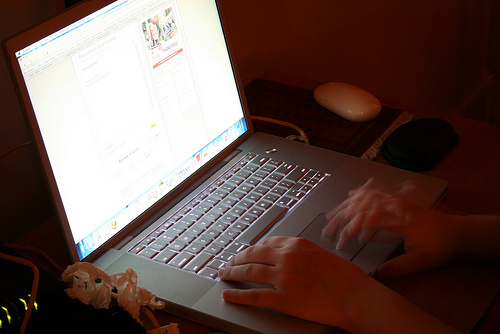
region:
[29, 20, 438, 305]
person working on lap top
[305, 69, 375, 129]
white computer mouse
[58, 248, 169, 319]
white tissue on side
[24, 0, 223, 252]
website on computer screen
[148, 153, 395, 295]
silver keyboard of lap top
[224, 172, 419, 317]
two hands on computer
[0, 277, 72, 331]
green power lights on table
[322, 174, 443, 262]
hand blurry from being in motion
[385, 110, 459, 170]
small black item on table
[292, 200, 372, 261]
mouse pad on lap top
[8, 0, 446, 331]
Silver laptop is lit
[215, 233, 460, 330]
Hand sitting on laptop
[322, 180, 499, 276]
Hand moving mouse pad of laptop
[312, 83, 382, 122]
White mouse next to laptop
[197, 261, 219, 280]
Silver key on keyboard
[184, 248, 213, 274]
Silver key on keyboard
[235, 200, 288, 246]
Silver key on keyboard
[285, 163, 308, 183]
Silver key on keyboard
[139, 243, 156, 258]
Silver key on keyboard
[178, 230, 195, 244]
Silver key on keyboard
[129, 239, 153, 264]
Black and white keys on the keyboard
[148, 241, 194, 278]
Black and white keys on the keyboard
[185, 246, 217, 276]
Black and white keys on the keyboard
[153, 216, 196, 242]
Black and white keys on the keyboard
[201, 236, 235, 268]
Black and white keys on the keyboard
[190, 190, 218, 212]
Black and white keys on the keyboard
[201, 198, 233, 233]
Black and white keys on the keyboard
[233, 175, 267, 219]
Black and white keys on the keyboard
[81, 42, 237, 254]
a laptop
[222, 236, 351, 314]
a persons hand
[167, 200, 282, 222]
the keyboard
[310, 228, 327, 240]
the electronic mouse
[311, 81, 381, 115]
the mouse is white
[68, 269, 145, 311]
tissue is white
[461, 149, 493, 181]
a desk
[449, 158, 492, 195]
the desk is wooden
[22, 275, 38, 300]
a white cord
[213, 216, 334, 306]
the hand of a person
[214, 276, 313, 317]
the pinky of a person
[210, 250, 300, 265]
the middle finger of a person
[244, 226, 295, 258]
the index finger of a person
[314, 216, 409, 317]
the wrist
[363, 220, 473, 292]
the thumb of a person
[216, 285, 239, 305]
the fingernail of a person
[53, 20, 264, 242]
the screen of a computer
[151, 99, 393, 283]
a keyboard on a desk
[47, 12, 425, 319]
a computer near a hand